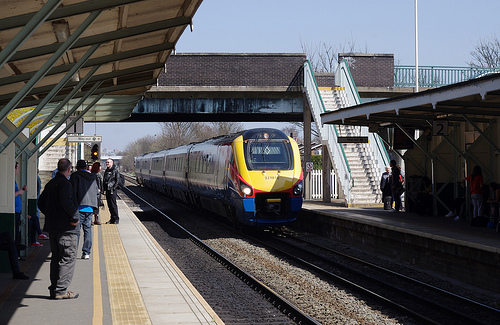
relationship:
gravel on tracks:
[225, 209, 347, 311] [133, 190, 299, 318]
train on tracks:
[128, 123, 321, 223] [133, 190, 299, 318]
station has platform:
[1, 2, 496, 323] [28, 169, 216, 324]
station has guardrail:
[1, 2, 496, 323] [391, 56, 499, 93]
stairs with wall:
[307, 62, 396, 206] [295, 58, 356, 209]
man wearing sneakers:
[72, 158, 97, 260] [81, 248, 94, 263]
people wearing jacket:
[38, 157, 78, 299] [36, 172, 84, 231]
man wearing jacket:
[72, 158, 97, 260] [72, 170, 104, 213]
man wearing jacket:
[99, 152, 122, 230] [103, 166, 123, 194]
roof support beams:
[4, 3, 161, 144] [8, 5, 95, 160]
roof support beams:
[311, 72, 500, 136] [354, 123, 497, 164]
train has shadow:
[128, 123, 321, 223] [123, 178, 232, 242]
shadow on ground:
[123, 178, 232, 242] [119, 198, 446, 325]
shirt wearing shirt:
[462, 164, 488, 227] [461, 170, 488, 197]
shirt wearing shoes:
[462, 164, 488, 227] [470, 212, 486, 227]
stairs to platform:
[307, 62, 396, 206] [307, 183, 497, 250]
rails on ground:
[133, 190, 299, 318] [119, 198, 446, 325]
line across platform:
[86, 195, 146, 324] [28, 169, 216, 324]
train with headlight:
[128, 123, 321, 223] [239, 181, 256, 198]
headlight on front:
[239, 181, 256, 198] [222, 125, 312, 230]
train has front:
[128, 123, 321, 223] [222, 125, 312, 230]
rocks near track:
[225, 209, 347, 311] [133, 190, 299, 318]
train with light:
[128, 123, 321, 223] [239, 181, 256, 198]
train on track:
[128, 123, 321, 223] [146, 190, 487, 323]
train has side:
[128, 123, 321, 223] [132, 140, 240, 193]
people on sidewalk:
[5, 139, 127, 305] [28, 169, 216, 324]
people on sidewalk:
[371, 149, 496, 230] [307, 183, 497, 250]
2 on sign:
[434, 122, 450, 137] [428, 117, 449, 136]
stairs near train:
[307, 62, 396, 206] [128, 123, 321, 223]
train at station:
[128, 123, 321, 223] [1, 2, 496, 323]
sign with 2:
[428, 117, 449, 136] [434, 122, 450, 137]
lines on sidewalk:
[86, 195, 146, 324] [28, 169, 216, 324]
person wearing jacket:
[99, 152, 122, 230] [103, 166, 123, 194]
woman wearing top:
[462, 164, 488, 227] [461, 170, 488, 197]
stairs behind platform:
[307, 62, 396, 206] [307, 183, 497, 250]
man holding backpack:
[99, 152, 122, 230] [113, 169, 125, 190]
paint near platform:
[86, 195, 146, 324] [28, 169, 216, 324]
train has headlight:
[128, 123, 321, 223] [239, 181, 256, 198]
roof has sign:
[4, 3, 161, 144] [333, 130, 385, 150]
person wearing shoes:
[27, 216, 49, 250] [30, 230, 50, 249]